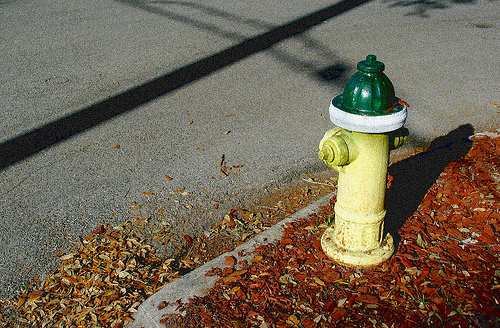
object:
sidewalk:
[0, 83, 500, 326]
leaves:
[141, 192, 155, 195]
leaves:
[233, 165, 242, 168]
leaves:
[112, 226, 124, 230]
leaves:
[184, 235, 191, 246]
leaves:
[303, 173, 314, 178]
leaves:
[165, 175, 173, 180]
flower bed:
[435, 173, 492, 313]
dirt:
[201, 270, 498, 323]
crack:
[0, 139, 103, 197]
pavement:
[0, 1, 500, 328]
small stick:
[302, 173, 337, 195]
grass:
[421, 295, 425, 305]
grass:
[447, 296, 457, 307]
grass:
[328, 215, 331, 224]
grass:
[315, 219, 320, 229]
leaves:
[211, 209, 271, 241]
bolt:
[390, 126, 407, 150]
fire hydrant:
[317, 55, 409, 270]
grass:
[404, 286, 415, 300]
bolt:
[365, 54, 377, 66]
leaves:
[0, 222, 193, 328]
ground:
[2, 1, 239, 133]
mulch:
[0, 113, 500, 328]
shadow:
[382, 0, 476, 18]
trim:
[329, 94, 408, 133]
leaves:
[386, 99, 411, 113]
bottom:
[320, 225, 394, 270]